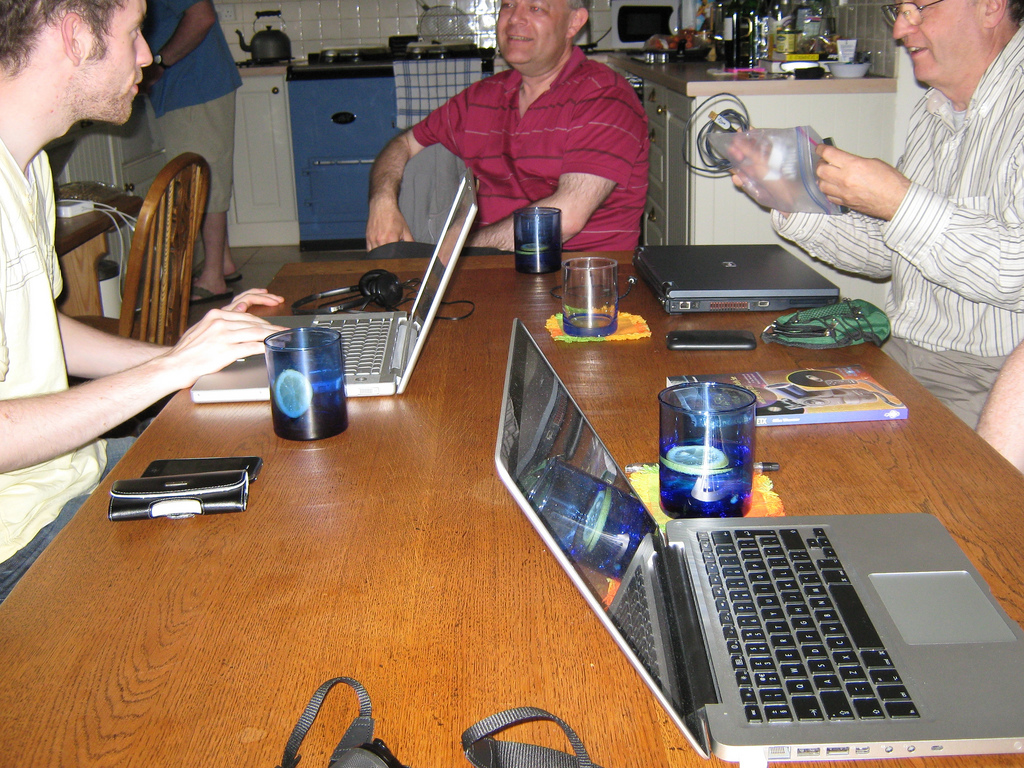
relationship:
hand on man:
[207, 284, 284, 313] [1, 0, 295, 599]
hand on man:
[169, 307, 291, 388] [1, 0, 295, 599]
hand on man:
[808, 138, 906, 221] [729, 2, 1021, 435]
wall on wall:
[217, 2, 930, 167] [217, 2, 931, 167]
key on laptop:
[781, 528, 808, 552] [637, 245, 838, 316]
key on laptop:
[791, 694, 823, 724] [492, 318, 1020, 761]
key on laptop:
[820, 688, 855, 721] [191, 170, 480, 406]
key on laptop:
[750, 656, 771, 670] [492, 318, 1020, 761]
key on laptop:
[748, 641, 774, 654] [492, 318, 1020, 761]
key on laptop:
[743, 625, 767, 642] [492, 318, 1020, 761]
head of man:
[889, 0, 1022, 84] [729, 2, 1020, 434]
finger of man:
[246, 289, 282, 311] [1, 0, 295, 599]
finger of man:
[238, 343, 268, 356] [1, 0, 295, 599]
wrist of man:
[154, 348, 206, 388] [1, 0, 295, 599]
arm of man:
[884, 130, 1020, 309] [729, 2, 1021, 435]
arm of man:
[465, 91, 637, 250] [367, 2, 653, 253]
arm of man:
[364, 94, 469, 249] [367, 2, 653, 253]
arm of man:
[56, 309, 177, 377] [1, 0, 295, 599]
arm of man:
[1, 354, 179, 473] [1, 0, 295, 599]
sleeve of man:
[882, 178, 1021, 315] [729, 2, 1021, 435]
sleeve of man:
[408, 85, 482, 149] [367, 2, 653, 253]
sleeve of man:
[560, 92, 621, 187] [367, 2, 653, 253]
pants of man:
[2, 495, 95, 597] [1, 0, 295, 599]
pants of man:
[879, 331, 1010, 430] [729, 2, 1021, 435]